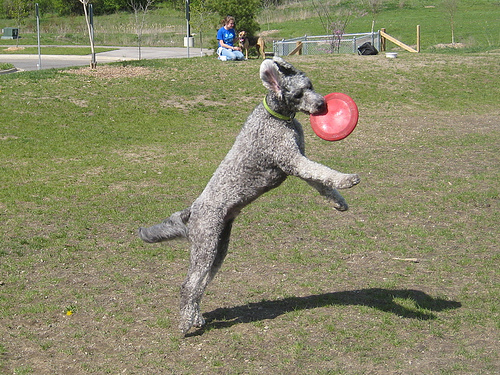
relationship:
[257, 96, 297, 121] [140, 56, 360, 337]
collar on dog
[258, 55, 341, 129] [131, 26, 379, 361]
face on dog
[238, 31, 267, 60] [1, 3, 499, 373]
dog in park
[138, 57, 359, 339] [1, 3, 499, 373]
dog in park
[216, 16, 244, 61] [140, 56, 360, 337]
woman next to dog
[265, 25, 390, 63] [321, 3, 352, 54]
fence surrounds small tree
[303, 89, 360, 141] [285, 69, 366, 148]
frisbee in mouth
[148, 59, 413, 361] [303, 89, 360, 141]
dog with frisbee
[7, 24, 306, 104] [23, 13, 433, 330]
concrete area in park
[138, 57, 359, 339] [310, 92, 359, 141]
dog holding frisbee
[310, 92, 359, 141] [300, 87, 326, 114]
frisbee in mouth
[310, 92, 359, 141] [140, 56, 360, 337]
frisbee in dog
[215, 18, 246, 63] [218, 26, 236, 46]
woman in blue shirt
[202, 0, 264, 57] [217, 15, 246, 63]
bush behind woman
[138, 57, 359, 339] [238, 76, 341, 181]
dog has collar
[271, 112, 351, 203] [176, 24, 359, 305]
front legs of dog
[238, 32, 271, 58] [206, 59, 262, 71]
dog on ground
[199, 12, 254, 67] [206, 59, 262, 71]
woman ground on ground